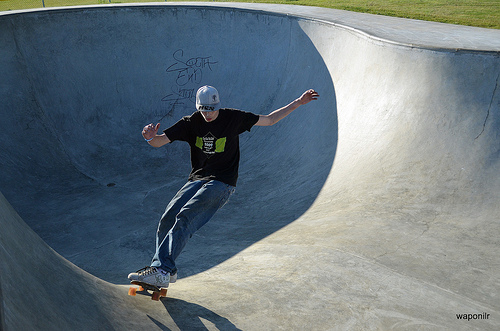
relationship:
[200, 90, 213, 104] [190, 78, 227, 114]
grey baseball cap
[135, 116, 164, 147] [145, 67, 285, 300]
hand of boy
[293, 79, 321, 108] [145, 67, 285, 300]
hand of boy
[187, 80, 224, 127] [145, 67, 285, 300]
head of boy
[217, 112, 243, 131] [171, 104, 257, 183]
black tee shirt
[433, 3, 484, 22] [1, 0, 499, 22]
green grassy field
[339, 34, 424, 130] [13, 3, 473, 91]
gray skate park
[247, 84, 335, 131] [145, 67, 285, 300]
arm of boy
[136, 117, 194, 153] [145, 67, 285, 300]
arms of boy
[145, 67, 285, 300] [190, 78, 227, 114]
skateboarder wearing hat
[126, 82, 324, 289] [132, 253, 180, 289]
boy wearing sneakers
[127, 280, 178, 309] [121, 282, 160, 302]
skateboard has wheels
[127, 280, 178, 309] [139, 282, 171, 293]
skateboard has wheels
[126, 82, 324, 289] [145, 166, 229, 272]
boy wearing jeans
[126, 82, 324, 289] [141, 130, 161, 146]
boy has bracelet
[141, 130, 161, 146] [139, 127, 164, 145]
bracelet on wrist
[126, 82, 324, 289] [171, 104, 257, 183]
boy wearing t-shirt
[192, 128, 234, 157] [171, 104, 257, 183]
design on shirt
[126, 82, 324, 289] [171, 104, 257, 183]
boy has shirt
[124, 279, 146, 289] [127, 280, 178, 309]
tip of skateboard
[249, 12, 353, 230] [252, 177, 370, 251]
shadow on ground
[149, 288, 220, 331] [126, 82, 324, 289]
shadow of boy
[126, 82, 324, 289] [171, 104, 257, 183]
boy wearing shirt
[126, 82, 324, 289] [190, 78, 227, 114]
boy wearing cap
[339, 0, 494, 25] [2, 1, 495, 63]
grass in background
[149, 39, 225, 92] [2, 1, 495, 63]
graffiti in background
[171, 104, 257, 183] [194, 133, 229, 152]
shirt has green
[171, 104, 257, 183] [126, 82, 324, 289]
shirt of boy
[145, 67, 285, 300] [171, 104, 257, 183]
man wearing shirt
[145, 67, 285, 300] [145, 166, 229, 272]
man wearing jeans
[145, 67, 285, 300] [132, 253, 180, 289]
man wearing shoes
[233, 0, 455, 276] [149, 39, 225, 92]
ramp has writing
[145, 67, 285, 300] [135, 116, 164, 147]
man has hand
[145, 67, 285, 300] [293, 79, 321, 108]
man has hand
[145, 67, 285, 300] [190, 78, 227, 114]
man wearing cap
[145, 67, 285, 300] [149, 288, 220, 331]
man casting shadow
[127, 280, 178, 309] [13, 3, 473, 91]
skateboard in park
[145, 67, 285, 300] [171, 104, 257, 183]
guy in shirt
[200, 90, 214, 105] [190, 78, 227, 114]
grey knit cap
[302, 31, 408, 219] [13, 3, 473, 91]
wall of park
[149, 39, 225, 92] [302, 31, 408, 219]
graffiti on wall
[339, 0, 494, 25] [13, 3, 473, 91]
grass above park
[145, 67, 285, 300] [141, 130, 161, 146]
boy wearing bracelet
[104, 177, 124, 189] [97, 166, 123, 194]
drain for water